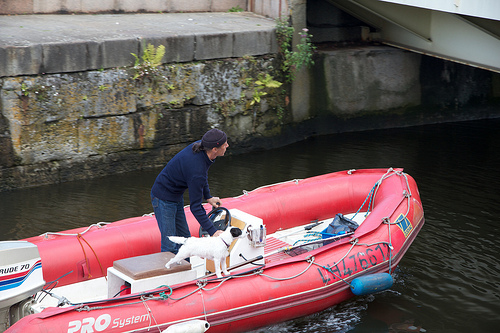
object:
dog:
[162, 228, 247, 278]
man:
[152, 127, 230, 255]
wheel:
[199, 206, 231, 238]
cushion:
[114, 249, 190, 280]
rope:
[350, 181, 378, 225]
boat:
[0, 165, 425, 332]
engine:
[0, 242, 47, 305]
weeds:
[133, 44, 166, 79]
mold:
[0, 86, 67, 120]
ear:
[233, 228, 240, 236]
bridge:
[349, 2, 499, 77]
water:
[427, 156, 500, 264]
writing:
[63, 310, 152, 332]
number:
[315, 240, 392, 288]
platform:
[0, 9, 281, 49]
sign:
[392, 212, 414, 239]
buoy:
[349, 272, 395, 295]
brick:
[3, 72, 136, 123]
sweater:
[148, 146, 220, 235]